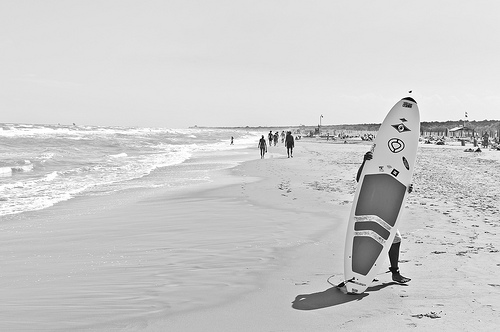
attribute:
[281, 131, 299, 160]
people — walking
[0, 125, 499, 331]
beach — sandy, scene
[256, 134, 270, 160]
people — walking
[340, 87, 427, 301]
surfboard — white, patterned, long, attached, designed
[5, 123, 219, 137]
waves — white, breaking, crashing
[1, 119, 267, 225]
ocean — white, moving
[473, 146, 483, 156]
people — laying, sitting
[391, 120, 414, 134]
markings — black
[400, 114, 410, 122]
markings — black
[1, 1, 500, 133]
sky — gray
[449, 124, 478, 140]
building — white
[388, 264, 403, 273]
bracelet — ankle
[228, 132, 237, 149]
child — standing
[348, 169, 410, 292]
pad — black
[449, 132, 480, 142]
area — picnic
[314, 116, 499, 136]
hills — background